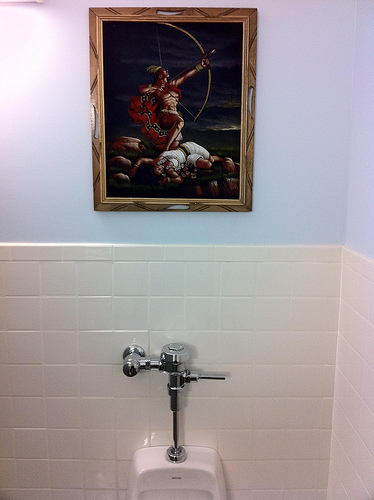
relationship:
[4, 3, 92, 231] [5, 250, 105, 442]
blue wall above tile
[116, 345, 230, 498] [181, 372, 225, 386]
toilet has flushing mechanism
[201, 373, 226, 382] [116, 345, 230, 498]
flush handle on toilet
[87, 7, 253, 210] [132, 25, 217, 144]
picture shows man with bow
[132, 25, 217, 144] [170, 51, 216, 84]
man with bow has arrow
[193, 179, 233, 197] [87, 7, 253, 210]
fruit on bottom of picture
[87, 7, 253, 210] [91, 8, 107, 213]
picture has frame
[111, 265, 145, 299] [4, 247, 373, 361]
tile on a wall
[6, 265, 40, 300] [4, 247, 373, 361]
tile part of row on wall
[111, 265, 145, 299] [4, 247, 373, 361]
tile on a tile line on wall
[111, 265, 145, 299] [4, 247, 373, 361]
tile part of bathroom wall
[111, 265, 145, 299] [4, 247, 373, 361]
tile affixed to wall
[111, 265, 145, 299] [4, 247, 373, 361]
tile attached to wall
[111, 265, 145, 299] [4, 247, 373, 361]
tile adding texture to wall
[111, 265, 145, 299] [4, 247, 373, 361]
tile above urinal on wall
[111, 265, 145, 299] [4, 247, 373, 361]
tile behind urinal on wall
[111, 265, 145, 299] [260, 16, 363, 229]
tile below blue wall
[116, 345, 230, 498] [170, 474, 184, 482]
urinal has writing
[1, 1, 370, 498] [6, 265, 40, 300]
scene shows white wall tile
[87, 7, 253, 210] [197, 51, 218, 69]
picture shows hand of man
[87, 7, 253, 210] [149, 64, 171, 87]
picture shows head of a ma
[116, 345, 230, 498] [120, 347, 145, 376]
urinal has pipe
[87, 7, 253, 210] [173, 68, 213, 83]
picture shows arm of a ma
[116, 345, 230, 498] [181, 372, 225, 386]
urinal has handle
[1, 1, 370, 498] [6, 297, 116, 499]
scene shows white tiles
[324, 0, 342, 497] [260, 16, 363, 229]
seam creating corner of wall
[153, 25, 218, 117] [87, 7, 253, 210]
bow and arrow are depicted on picture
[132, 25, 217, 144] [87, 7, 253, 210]
warrior depicted on picture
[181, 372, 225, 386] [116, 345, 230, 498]
flusher handle on urinal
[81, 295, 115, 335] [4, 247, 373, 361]
white tile decorates wall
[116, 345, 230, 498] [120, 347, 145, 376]
urinal has metal pipe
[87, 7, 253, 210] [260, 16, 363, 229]
painting hanging upon a wall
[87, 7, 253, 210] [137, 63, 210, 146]
picture includes arm of man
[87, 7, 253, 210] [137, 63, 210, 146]
picture includes head of man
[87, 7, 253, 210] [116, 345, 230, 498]
picture above toilet